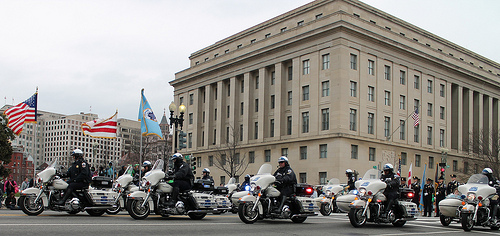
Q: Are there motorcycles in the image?
A: Yes, there is a motorcycle.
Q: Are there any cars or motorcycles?
A: Yes, there is a motorcycle.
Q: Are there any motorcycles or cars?
A: Yes, there is a motorcycle.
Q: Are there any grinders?
A: No, there are no grinders.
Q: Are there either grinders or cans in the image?
A: No, there are no grinders or cans.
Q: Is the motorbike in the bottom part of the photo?
A: Yes, the motorbike is in the bottom of the image.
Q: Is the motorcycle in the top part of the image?
A: No, the motorcycle is in the bottom of the image.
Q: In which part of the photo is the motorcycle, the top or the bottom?
A: The motorcycle is in the bottom of the image.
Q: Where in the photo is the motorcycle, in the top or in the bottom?
A: The motorcycle is in the bottom of the image.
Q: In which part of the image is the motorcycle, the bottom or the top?
A: The motorcycle is in the bottom of the image.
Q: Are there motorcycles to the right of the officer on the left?
A: Yes, there is a motorcycle to the right of the officer.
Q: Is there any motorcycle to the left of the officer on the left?
A: No, the motorcycle is to the right of the officer.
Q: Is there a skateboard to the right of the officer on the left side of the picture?
A: No, there is a motorcycle to the right of the officer.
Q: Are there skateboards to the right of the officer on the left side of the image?
A: No, there is a motorcycle to the right of the officer.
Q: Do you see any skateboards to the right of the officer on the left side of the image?
A: No, there is a motorcycle to the right of the officer.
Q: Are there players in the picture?
A: No, there are no players.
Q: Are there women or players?
A: No, there are no players or women.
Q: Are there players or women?
A: No, there are no players or women.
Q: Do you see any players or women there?
A: No, there are no players or women.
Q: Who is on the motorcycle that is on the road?
A: The officer is on the motorbike.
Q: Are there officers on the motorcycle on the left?
A: Yes, there is an officer on the motorbike.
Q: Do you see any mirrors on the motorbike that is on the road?
A: No, there is an officer on the motorcycle.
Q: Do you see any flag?
A: Yes, there is a flag.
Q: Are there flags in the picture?
A: Yes, there is a flag.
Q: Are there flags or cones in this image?
A: Yes, there is a flag.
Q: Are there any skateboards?
A: No, there are no skateboards.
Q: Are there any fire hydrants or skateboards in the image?
A: No, there are no skateboards or fire hydrants.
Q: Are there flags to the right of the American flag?
A: Yes, there is a flag to the right of the American flag.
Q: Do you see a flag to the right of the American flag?
A: Yes, there is a flag to the right of the American flag.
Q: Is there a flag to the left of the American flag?
A: No, the flag is to the right of the American flag.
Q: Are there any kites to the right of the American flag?
A: No, there is a flag to the right of the American flag.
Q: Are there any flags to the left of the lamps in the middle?
A: Yes, there is a flag to the left of the lamps.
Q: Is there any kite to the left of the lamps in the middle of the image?
A: No, there is a flag to the left of the lamps.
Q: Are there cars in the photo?
A: No, there are no cars.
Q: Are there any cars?
A: No, there are no cars.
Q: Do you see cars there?
A: No, there are no cars.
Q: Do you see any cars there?
A: No, there are no cars.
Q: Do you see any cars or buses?
A: No, there are no cars or buses.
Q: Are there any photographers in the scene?
A: No, there are no photographers.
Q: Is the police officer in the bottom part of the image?
A: Yes, the police officer is in the bottom of the image.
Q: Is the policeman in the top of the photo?
A: No, the policeman is in the bottom of the image.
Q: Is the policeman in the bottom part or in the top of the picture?
A: The policeman is in the bottom of the image.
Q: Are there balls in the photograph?
A: No, there are no balls.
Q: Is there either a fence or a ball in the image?
A: No, there are no balls or fences.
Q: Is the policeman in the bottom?
A: Yes, the policeman is in the bottom of the image.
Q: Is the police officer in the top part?
A: No, the police officer is in the bottom of the image.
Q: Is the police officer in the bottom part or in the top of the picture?
A: The police officer is in the bottom of the image.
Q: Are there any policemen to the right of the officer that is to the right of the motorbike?
A: Yes, there is a policeman to the right of the officer.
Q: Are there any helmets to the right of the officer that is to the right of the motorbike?
A: No, there is a policeman to the right of the officer.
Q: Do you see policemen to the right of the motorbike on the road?
A: Yes, there is a policeman to the right of the motorbike.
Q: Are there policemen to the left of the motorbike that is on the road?
A: No, the policeman is to the right of the motorcycle.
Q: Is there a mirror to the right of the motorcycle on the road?
A: No, there is a policeman to the right of the motorbike.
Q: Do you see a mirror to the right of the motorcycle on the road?
A: No, there is a policeman to the right of the motorbike.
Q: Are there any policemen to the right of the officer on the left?
A: Yes, there is a policeman to the right of the officer.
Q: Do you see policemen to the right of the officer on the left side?
A: Yes, there is a policeman to the right of the officer.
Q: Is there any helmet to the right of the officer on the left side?
A: No, there is a policeman to the right of the officer.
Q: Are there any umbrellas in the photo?
A: No, there are no umbrellas.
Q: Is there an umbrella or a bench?
A: No, there are no umbrellas or benches.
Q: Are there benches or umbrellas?
A: No, there are no umbrellas or benches.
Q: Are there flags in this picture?
A: Yes, there is a flag.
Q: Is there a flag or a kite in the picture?
A: Yes, there is a flag.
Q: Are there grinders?
A: No, there are no grinders.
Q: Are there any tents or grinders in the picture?
A: No, there are no grinders or tents.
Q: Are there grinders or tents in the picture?
A: No, there are no grinders or tents.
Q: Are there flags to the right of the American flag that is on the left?
A: Yes, there is a flag to the right of the American flag.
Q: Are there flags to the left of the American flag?
A: No, the flag is to the right of the American flag.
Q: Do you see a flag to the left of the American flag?
A: No, the flag is to the right of the American flag.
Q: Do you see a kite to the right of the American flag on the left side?
A: No, there is a flag to the right of the American flag.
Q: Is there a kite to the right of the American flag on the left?
A: No, there is a flag to the right of the American flag.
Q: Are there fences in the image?
A: No, there are no fences.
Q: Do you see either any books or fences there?
A: No, there are no fences or books.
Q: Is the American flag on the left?
A: Yes, the American flag is on the left of the image.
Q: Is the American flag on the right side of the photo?
A: No, the American flag is on the left of the image.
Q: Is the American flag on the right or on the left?
A: The American flag is on the left of the image.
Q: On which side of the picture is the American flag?
A: The American flag is on the left of the image.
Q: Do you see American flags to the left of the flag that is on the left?
A: Yes, there is an American flag to the left of the flag.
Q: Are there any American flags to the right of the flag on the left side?
A: No, the American flag is to the left of the flag.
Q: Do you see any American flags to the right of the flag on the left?
A: No, the American flag is to the left of the flag.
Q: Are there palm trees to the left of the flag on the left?
A: No, there is an American flag to the left of the flag.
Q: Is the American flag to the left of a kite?
A: No, the American flag is to the left of a flag.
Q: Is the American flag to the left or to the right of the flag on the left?
A: The American flag is to the left of the flag.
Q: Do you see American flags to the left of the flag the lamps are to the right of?
A: Yes, there is an American flag to the left of the flag.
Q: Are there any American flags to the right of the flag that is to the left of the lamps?
A: No, the American flag is to the left of the flag.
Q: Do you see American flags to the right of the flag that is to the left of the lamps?
A: No, the American flag is to the left of the flag.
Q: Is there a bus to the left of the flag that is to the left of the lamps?
A: No, there is an American flag to the left of the flag.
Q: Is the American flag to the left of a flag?
A: Yes, the American flag is to the left of a flag.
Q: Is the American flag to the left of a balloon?
A: No, the American flag is to the left of a flag.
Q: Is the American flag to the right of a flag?
A: No, the American flag is to the left of a flag.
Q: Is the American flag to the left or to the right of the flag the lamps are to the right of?
A: The American flag is to the left of the flag.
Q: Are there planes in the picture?
A: No, there are no planes.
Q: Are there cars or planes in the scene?
A: No, there are no planes or cars.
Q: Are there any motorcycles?
A: Yes, there is a motorcycle.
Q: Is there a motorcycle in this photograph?
A: Yes, there is a motorcycle.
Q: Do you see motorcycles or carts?
A: Yes, there is a motorcycle.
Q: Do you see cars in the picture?
A: No, there are no cars.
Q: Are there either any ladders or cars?
A: No, there are no cars or ladders.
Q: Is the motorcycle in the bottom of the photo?
A: Yes, the motorcycle is in the bottom of the image.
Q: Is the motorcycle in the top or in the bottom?
A: The motorcycle is in the bottom of the image.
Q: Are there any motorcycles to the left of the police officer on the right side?
A: Yes, there is a motorcycle to the left of the police officer.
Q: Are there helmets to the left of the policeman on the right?
A: No, there is a motorcycle to the left of the police officer.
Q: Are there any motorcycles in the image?
A: Yes, there is a motorcycle.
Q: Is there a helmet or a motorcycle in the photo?
A: Yes, there is a motorcycle.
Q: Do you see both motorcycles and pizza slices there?
A: No, there is a motorcycle but no pizza slices.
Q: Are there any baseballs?
A: No, there are no baseballs.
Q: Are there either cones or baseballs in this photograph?
A: No, there are no baseballs or cones.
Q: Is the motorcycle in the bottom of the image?
A: Yes, the motorcycle is in the bottom of the image.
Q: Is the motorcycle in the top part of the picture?
A: No, the motorcycle is in the bottom of the image.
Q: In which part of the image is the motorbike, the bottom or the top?
A: The motorbike is in the bottom of the image.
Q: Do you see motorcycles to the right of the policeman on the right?
A: Yes, there is a motorcycle to the right of the policeman.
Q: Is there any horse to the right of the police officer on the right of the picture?
A: No, there is a motorcycle to the right of the police officer.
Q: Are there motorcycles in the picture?
A: Yes, there is a motorcycle.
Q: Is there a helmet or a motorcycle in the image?
A: Yes, there is a motorcycle.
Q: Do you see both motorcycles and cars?
A: No, there is a motorcycle but no cars.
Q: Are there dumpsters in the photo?
A: No, there are no dumpsters.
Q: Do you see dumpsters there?
A: No, there are no dumpsters.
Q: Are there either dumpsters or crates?
A: No, there are no dumpsters or crates.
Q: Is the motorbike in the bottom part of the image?
A: Yes, the motorbike is in the bottom of the image.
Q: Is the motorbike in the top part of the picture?
A: No, the motorbike is in the bottom of the image.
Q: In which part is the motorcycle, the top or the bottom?
A: The motorcycle is in the bottom of the image.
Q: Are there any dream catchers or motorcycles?
A: Yes, there is a motorcycle.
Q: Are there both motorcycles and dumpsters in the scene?
A: No, there is a motorcycle but no dumpsters.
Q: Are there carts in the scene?
A: No, there are no carts.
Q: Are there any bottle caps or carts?
A: No, there are no carts or bottle caps.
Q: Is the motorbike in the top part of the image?
A: No, the motorbike is in the bottom of the image.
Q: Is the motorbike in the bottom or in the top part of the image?
A: The motorbike is in the bottom of the image.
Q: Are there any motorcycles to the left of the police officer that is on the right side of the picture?
A: Yes, there is a motorcycle to the left of the policeman.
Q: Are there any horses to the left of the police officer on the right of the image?
A: No, there is a motorcycle to the left of the police officer.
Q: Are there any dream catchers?
A: No, there are no dream catchers.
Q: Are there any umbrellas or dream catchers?
A: No, there are no dream catchers or umbrellas.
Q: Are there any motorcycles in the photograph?
A: Yes, there is a motorcycle.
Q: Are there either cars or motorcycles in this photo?
A: Yes, there is a motorcycle.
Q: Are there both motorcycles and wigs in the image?
A: No, there is a motorcycle but no wigs.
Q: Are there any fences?
A: No, there are no fences.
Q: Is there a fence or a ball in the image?
A: No, there are no fences or balls.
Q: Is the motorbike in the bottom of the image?
A: Yes, the motorbike is in the bottom of the image.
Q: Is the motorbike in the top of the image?
A: No, the motorbike is in the bottom of the image.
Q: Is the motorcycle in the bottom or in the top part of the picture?
A: The motorcycle is in the bottom of the image.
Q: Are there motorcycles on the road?
A: Yes, there is a motorcycle on the road.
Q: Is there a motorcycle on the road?
A: Yes, there is a motorcycle on the road.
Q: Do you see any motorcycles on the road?
A: Yes, there is a motorcycle on the road.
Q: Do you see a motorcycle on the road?
A: Yes, there is a motorcycle on the road.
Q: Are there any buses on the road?
A: No, there is a motorcycle on the road.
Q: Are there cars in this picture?
A: No, there are no cars.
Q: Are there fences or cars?
A: No, there are no cars or fences.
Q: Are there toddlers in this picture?
A: No, there are no toddlers.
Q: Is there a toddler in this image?
A: No, there are no toddlers.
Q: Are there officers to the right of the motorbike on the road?
A: Yes, there is an officer to the right of the motorcycle.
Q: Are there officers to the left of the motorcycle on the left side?
A: No, the officer is to the right of the motorbike.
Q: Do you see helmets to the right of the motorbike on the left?
A: No, there is an officer to the right of the motorcycle.